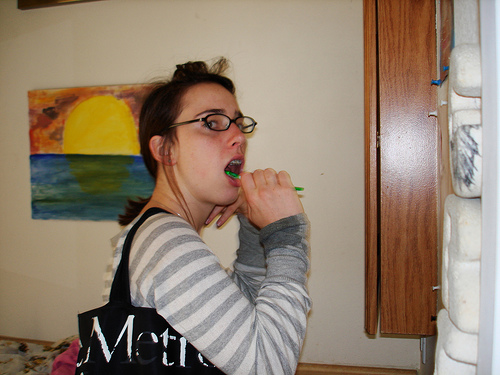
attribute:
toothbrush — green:
[220, 163, 342, 225]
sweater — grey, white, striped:
[95, 203, 315, 370]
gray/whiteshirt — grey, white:
[102, 208, 324, 373]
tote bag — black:
[74, 298, 234, 373]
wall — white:
[10, 11, 422, 352]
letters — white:
[75, 316, 212, 368]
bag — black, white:
[72, 300, 207, 372]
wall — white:
[283, 11, 347, 181]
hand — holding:
[235, 167, 306, 232]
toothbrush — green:
[223, 169, 303, 193]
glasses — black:
[139, 111, 264, 141]